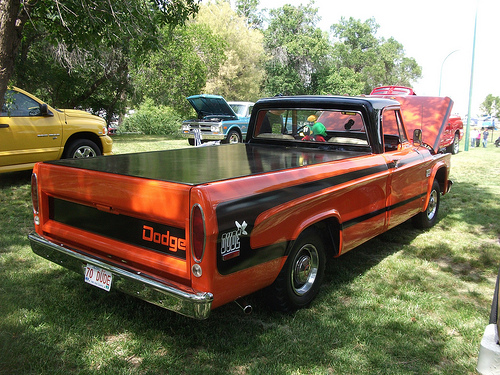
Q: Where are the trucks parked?
A: On the grass.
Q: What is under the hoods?
A: Engines.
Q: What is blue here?
A: A truck.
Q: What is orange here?
A: A truck.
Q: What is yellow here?
A: A truck.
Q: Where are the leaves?
A: On the trees.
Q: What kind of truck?
A: Dodge.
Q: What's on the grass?
A: Trucks.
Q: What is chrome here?
A: Bumper.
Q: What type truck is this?
A: Older model.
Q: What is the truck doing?
A: It is parked.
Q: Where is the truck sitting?
A: On the grass.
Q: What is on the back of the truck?
A: License plate.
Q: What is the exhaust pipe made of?
A: Chrome.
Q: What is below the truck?
A: Grass.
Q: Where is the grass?
A: Below the truck.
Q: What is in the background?
A: Many trees.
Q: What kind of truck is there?
A: Orange.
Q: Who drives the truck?
A: A man.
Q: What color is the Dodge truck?
A: Orange.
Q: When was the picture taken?
A: During a car show.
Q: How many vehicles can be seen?
A: Four.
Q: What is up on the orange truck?
A: Hood.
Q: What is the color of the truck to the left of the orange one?
A: Yellow.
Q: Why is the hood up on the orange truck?
A: Looking under the hood.